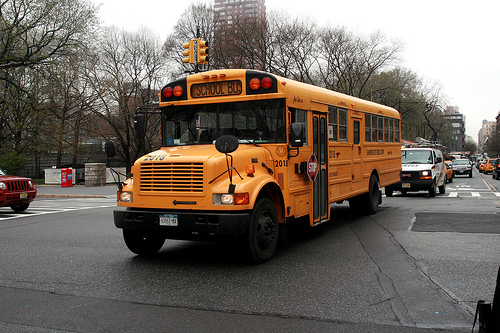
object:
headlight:
[219, 192, 235, 205]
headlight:
[118, 190, 132, 203]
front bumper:
[111, 207, 252, 236]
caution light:
[247, 76, 261, 91]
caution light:
[260, 75, 273, 89]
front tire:
[234, 196, 281, 263]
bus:
[105, 67, 404, 261]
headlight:
[421, 170, 430, 177]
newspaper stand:
[59, 167, 70, 187]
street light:
[180, 33, 211, 66]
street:
[402, 232, 479, 290]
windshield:
[159, 96, 285, 145]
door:
[311, 110, 330, 221]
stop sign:
[304, 153, 318, 182]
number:
[273, 157, 291, 167]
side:
[280, 76, 401, 232]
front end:
[0, 177, 37, 216]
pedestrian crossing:
[442, 184, 484, 201]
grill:
[136, 161, 210, 198]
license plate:
[156, 213, 179, 226]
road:
[338, 284, 432, 330]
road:
[441, 243, 466, 244]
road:
[6, 272, 45, 311]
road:
[55, 219, 74, 222]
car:
[384, 147, 445, 196]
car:
[439, 160, 454, 182]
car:
[451, 154, 472, 180]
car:
[0, 158, 33, 212]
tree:
[4, 1, 68, 183]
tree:
[40, 27, 87, 173]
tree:
[83, 34, 153, 177]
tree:
[132, 33, 157, 162]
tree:
[163, 3, 240, 72]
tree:
[231, 14, 293, 78]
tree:
[260, 8, 314, 74]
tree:
[320, 34, 399, 99]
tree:
[376, 67, 416, 142]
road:
[12, 304, 119, 324]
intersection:
[47, 177, 484, 316]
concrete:
[461, 272, 485, 324]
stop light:
[174, 29, 215, 69]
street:
[12, 65, 482, 327]